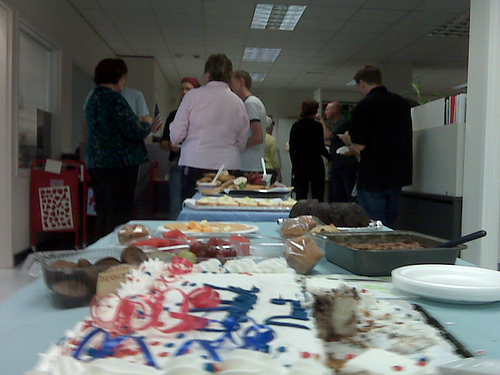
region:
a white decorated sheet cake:
[29, 260, 473, 373]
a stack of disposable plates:
[390, 264, 498, 306]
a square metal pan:
[312, 230, 466, 275]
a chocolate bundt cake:
[289, 197, 367, 227]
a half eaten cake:
[40, 256, 470, 373]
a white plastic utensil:
[210, 162, 225, 182]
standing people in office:
[3, 0, 497, 371]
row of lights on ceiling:
[80, 2, 469, 85]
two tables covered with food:
[1, 173, 498, 372]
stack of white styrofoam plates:
[390, 262, 498, 305]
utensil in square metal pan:
[318, 225, 487, 279]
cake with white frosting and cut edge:
[38, 257, 333, 374]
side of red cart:
[27, 156, 82, 253]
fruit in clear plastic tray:
[133, 227, 280, 264]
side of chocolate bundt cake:
[278, 199, 375, 233]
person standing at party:
[177, 52, 259, 162]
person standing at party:
[58, 53, 150, 188]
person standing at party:
[137, 63, 198, 185]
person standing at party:
[228, 68, 266, 176]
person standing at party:
[291, 86, 329, 184]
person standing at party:
[325, 101, 336, 189]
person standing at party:
[352, 66, 407, 196]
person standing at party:
[260, 105, 290, 183]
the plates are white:
[390, 259, 498, 313]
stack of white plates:
[394, 274, 496, 304]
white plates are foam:
[404, 258, 496, 313]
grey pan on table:
[322, 224, 444, 261]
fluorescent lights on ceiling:
[242, 1, 304, 31]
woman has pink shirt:
[176, 99, 221, 154]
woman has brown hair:
[205, 44, 230, 83]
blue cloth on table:
[100, 220, 459, 372]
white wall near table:
[465, 95, 491, 132]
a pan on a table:
[369, 230, 478, 310]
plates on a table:
[408, 263, 499, 340]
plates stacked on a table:
[378, 234, 497, 326]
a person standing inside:
[164, 42, 269, 195]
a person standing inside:
[223, 66, 272, 163]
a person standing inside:
[168, 66, 210, 147]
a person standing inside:
[323, 95, 347, 177]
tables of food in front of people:
[7, 50, 491, 370]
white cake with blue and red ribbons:
[32, 252, 363, 369]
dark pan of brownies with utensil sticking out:
[320, 213, 488, 273]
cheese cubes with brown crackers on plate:
[158, 213, 258, 243]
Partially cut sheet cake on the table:
[35, 261, 384, 373]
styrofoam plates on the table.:
[393, 262, 498, 305]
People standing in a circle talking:
[83, 53, 267, 221]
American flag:
[150, 98, 163, 142]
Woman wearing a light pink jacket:
[167, 49, 249, 195]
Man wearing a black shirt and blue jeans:
[340, 66, 417, 225]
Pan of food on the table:
[316, 226, 468, 276]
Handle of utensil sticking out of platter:
[433, 231, 488, 253]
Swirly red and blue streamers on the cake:
[81, 287, 273, 357]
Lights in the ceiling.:
[238, 0, 310, 87]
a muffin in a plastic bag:
[280, 228, 322, 272]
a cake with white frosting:
[87, 245, 330, 366]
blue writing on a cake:
[262, 288, 317, 345]